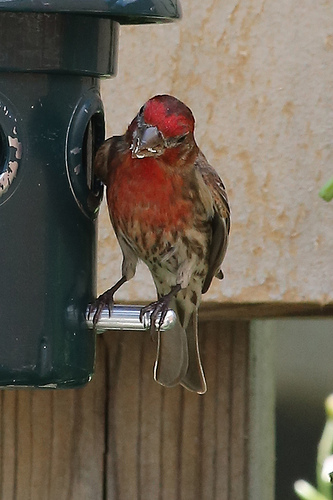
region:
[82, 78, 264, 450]
This is a bird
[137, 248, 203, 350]
Leg of a bird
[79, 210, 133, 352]
Leg of a bird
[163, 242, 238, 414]
Tail of a bird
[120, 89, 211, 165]
Head of a bird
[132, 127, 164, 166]
Peak of a bird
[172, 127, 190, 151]
Eye of a bird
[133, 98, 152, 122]
Eye of a bird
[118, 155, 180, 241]
Chest of a bird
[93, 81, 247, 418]
A red and brown bird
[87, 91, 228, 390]
bird sitting by feeder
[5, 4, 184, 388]
feeder is grey and worn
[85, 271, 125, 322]
black foot of bird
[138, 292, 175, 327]
black foot of bird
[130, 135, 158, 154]
beak of the bird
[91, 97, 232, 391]
bird is perched and eating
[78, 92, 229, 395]
birds head is tilted sideways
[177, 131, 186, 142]
black eye of bird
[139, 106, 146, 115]
black eye of bird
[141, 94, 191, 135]
red head of bird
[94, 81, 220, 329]
Bird standing on a birdhouse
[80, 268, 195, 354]
Bird standing on a birdhouse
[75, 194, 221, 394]
Bird standing on a birdhouse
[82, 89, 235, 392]
red bird perched on silver handle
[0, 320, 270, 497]
wooden wall made of slats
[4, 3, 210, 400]
green metal bird feeder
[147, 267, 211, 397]
long gray tail of red bird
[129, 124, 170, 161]
open beak of red bird eating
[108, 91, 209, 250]
front of red bird perched on feeder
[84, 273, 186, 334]
black claws on red bird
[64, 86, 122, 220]
hole in green bird feeder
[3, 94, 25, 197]
hole in bird feeder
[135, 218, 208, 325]
gray spotted feathers of bird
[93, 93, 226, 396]
bird on feeder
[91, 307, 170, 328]
silver pole for bird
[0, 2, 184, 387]
dark and worn feeder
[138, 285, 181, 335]
foot of a bird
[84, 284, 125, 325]
foot of a bird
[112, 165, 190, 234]
red chest of bird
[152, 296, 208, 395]
tail of a pird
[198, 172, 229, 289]
wing of bird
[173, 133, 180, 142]
eye of bird perched by feeder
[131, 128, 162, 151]
beak of bird perched by feeder